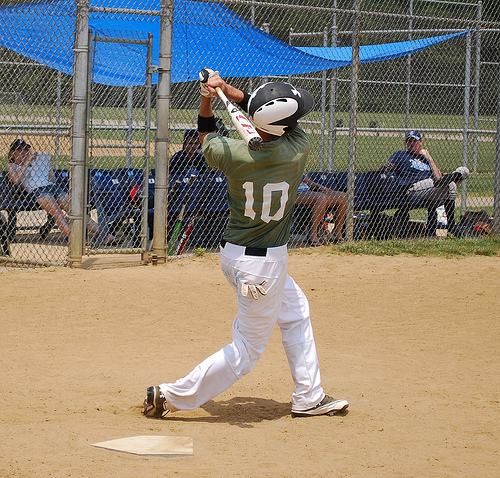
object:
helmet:
[242, 79, 315, 137]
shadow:
[160, 393, 291, 429]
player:
[139, 65, 348, 419]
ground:
[0, 105, 499, 477]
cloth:
[0, 1, 475, 89]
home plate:
[92, 431, 194, 457]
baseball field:
[0, 232, 499, 477]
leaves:
[26, 75, 42, 91]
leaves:
[443, 54, 459, 70]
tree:
[0, 0, 498, 118]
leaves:
[386, 61, 401, 76]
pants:
[156, 236, 326, 415]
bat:
[210, 84, 264, 153]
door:
[83, 29, 150, 253]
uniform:
[155, 126, 329, 415]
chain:
[121, 79, 135, 177]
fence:
[0, 0, 499, 268]